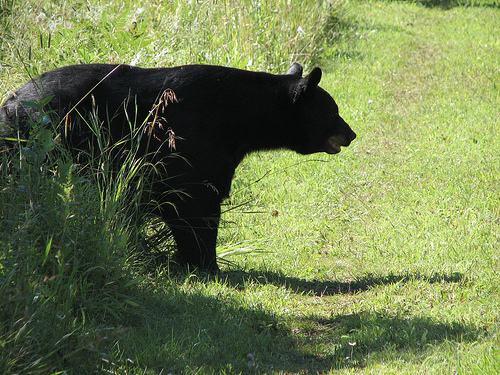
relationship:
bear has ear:
[1, 61, 358, 271] [286, 62, 303, 76]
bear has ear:
[1, 61, 358, 271] [304, 68, 323, 88]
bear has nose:
[1, 61, 358, 271] [351, 131, 356, 140]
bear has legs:
[1, 61, 358, 271] [152, 206, 221, 273]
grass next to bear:
[1, 135, 29, 143] [1, 61, 358, 271]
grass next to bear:
[74, 106, 97, 137] [1, 61, 358, 271]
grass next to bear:
[132, 95, 139, 127] [1, 61, 358, 271]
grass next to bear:
[220, 198, 254, 212] [1, 61, 358, 271]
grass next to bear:
[230, 159, 331, 199] [1, 61, 358, 271]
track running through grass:
[320, 14, 440, 316] [0, 0, 498, 374]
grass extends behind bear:
[0, 0, 498, 374] [1, 61, 358, 271]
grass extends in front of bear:
[0, 0, 498, 374] [1, 61, 358, 271]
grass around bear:
[0, 0, 498, 374] [1, 61, 358, 271]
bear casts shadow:
[1, 61, 358, 271] [147, 251, 465, 297]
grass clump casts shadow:
[1, 58, 232, 324] [2, 278, 490, 374]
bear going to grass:
[1, 61, 358, 271] [0, 0, 498, 374]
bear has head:
[1, 61, 358, 271] [284, 62, 358, 155]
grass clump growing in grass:
[1, 58, 232, 324] [0, 0, 498, 374]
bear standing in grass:
[1, 61, 358, 271] [0, 0, 498, 374]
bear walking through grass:
[1, 61, 358, 271] [0, 0, 498, 374]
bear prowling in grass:
[1, 61, 358, 271] [0, 0, 498, 374]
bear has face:
[1, 61, 358, 271] [318, 87, 358, 155]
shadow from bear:
[147, 251, 465, 297] [1, 61, 358, 271]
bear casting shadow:
[1, 61, 358, 271] [147, 251, 465, 297]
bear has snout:
[1, 61, 358, 271] [325, 115, 357, 154]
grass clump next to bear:
[1, 58, 232, 324] [1, 61, 358, 271]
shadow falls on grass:
[147, 251, 465, 297] [0, 0, 498, 374]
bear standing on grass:
[1, 61, 358, 271] [0, 0, 498, 374]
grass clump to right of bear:
[1, 58, 232, 324] [1, 61, 358, 271]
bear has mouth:
[1, 61, 358, 271] [328, 133, 349, 151]